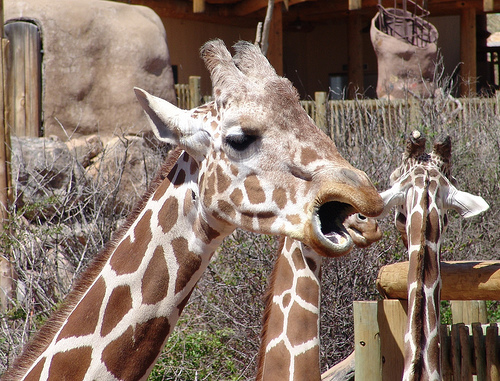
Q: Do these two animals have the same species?
A: Yes, all the animals are giraffes.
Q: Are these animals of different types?
A: No, all the animals are giraffes.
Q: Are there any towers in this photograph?
A: No, there are no towers.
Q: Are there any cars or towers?
A: No, there are no towers or cars.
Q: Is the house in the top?
A: Yes, the house is in the top of the image.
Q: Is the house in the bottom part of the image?
A: No, the house is in the top of the image.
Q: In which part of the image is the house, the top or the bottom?
A: The house is in the top of the image.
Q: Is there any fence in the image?
A: Yes, there is a fence.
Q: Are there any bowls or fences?
A: Yes, there is a fence.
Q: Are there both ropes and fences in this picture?
A: No, there is a fence but no ropes.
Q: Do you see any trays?
A: No, there are no trays.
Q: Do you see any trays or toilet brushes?
A: No, there are no trays or toilet brushes.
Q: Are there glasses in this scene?
A: No, there are no glasses.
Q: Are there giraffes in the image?
A: Yes, there is a giraffe.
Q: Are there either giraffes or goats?
A: Yes, there is a giraffe.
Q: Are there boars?
A: No, there are no boars.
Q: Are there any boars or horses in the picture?
A: No, there are no boars or horses.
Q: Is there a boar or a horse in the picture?
A: No, there are no boars or horses.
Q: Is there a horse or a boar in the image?
A: No, there are no boars or horses.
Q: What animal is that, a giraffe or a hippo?
A: That is a giraffe.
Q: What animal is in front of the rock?
A: The giraffe is in front of the rock.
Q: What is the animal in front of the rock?
A: The animal is a giraffe.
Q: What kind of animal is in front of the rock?
A: The animal is a giraffe.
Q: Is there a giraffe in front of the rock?
A: Yes, there is a giraffe in front of the rock.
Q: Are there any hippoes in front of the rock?
A: No, there is a giraffe in front of the rock.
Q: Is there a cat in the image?
A: No, there are no cats.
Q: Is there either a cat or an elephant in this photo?
A: No, there are no cats or elephants.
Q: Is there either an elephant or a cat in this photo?
A: No, there are no cats or elephants.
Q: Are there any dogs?
A: No, there are no dogs.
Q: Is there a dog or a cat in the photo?
A: No, there are no dogs or cats.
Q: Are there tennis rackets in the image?
A: No, there are no tennis rackets.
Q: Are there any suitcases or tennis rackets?
A: No, there are no tennis rackets or suitcases.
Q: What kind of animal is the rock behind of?
A: The rock is behind the giraffe.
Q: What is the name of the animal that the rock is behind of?
A: The animal is a giraffe.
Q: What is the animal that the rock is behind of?
A: The animal is a giraffe.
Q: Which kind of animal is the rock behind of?
A: The rock is behind the giraffe.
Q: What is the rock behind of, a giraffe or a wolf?
A: The rock is behind a giraffe.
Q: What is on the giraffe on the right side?
A: The spots are on the giraffe.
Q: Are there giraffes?
A: Yes, there is a giraffe.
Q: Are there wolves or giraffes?
A: Yes, there is a giraffe.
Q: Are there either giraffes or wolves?
A: Yes, there is a giraffe.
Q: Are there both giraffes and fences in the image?
A: Yes, there are both a giraffe and a fence.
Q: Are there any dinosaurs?
A: No, there are no dinosaurs.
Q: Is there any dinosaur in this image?
A: No, there are no dinosaurs.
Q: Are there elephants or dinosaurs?
A: No, there are no dinosaurs or elephants.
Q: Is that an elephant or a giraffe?
A: That is a giraffe.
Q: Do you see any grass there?
A: Yes, there is grass.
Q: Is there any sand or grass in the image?
A: Yes, there is grass.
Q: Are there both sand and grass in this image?
A: No, there is grass but no sand.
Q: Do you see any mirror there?
A: No, there are no mirrors.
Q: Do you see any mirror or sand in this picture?
A: No, there are no mirrors or sand.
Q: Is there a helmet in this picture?
A: No, there are no helmets.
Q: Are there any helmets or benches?
A: No, there are no helmets or benches.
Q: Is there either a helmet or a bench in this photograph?
A: No, there are no helmets or benches.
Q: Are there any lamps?
A: No, there are no lamps.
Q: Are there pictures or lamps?
A: No, there are no lamps or pictures.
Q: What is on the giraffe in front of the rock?
A: The spots are on the giraffe.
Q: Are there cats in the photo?
A: No, there are no cats.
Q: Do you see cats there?
A: No, there are no cats.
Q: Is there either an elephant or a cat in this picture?
A: No, there are no cats or elephants.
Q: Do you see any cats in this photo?
A: No, there are no cats.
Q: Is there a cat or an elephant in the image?
A: No, there are no cats or elephants.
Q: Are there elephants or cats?
A: No, there are no cats or elephants.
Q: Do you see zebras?
A: No, there are no zebras.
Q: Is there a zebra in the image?
A: No, there are no zebras.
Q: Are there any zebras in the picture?
A: No, there are no zebras.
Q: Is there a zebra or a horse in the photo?
A: No, there are no zebras or horses.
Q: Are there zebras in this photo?
A: No, there are no zebras.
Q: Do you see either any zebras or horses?
A: No, there are no zebras or horses.